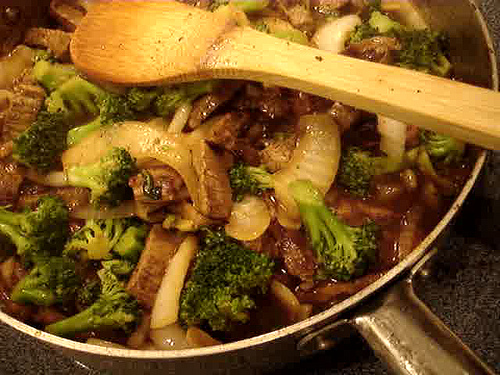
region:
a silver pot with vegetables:
[7, 7, 469, 364]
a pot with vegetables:
[14, 14, 469, 351]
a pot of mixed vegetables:
[4, 7, 476, 357]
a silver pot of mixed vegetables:
[22, 10, 498, 361]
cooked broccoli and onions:
[42, 82, 422, 261]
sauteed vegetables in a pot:
[17, 19, 464, 330]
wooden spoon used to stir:
[14, 0, 451, 175]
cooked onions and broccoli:
[7, 15, 467, 367]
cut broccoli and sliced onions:
[34, 35, 375, 257]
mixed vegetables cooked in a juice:
[40, 37, 411, 280]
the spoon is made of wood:
[70, 3, 491, 242]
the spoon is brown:
[76, 3, 495, 226]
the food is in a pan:
[1, 1, 485, 370]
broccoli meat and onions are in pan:
[3, 0, 440, 374]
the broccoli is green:
[1, 41, 431, 363]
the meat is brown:
[46, 88, 443, 280]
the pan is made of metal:
[2, 0, 472, 367]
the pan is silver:
[1, 0, 479, 357]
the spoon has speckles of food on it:
[74, 0, 475, 151]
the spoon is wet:
[70, 6, 247, 91]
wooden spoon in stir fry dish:
[51, 3, 476, 179]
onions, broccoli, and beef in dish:
[16, 102, 406, 350]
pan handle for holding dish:
[255, 228, 487, 356]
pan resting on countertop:
[316, 190, 474, 363]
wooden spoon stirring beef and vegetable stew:
[36, 12, 426, 244]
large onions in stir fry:
[81, 113, 358, 263]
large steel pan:
[17, 282, 480, 367]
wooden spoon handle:
[288, 26, 486, 188]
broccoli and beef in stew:
[8, 25, 112, 225]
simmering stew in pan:
[251, 98, 471, 324]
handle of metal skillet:
[295, 256, 492, 367]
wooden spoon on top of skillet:
[76, 0, 497, 150]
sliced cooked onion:
[269, 92, 339, 205]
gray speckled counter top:
[434, 222, 499, 352]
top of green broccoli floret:
[178, 231, 255, 312]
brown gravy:
[353, 155, 438, 225]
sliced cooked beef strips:
[185, 125, 242, 225]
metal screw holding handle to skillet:
[400, 251, 443, 284]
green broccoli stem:
[277, 166, 350, 237]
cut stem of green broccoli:
[49, 207, 131, 261]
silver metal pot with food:
[64, 253, 498, 348]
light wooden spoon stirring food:
[70, 10, 495, 248]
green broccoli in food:
[4, 110, 409, 365]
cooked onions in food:
[32, 116, 366, 261]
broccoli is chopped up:
[41, 96, 177, 304]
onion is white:
[255, 133, 342, 200]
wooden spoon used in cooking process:
[68, 20, 498, 161]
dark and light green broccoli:
[268, 194, 378, 273]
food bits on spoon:
[120, 25, 200, 57]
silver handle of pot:
[309, 274, 488, 354]